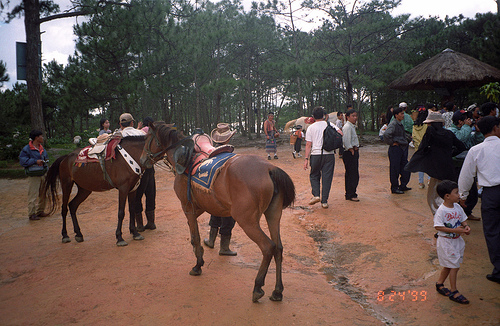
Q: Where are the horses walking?
A: On dirt.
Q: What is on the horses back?
A: Saddle.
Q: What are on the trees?
A: Gree leaves.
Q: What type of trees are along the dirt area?
A: Pine trees.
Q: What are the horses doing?
A: Standing.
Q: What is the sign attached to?
A: A tree.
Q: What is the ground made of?
A: Red clay.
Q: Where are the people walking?
A: On red clay.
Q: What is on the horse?
A: A saddle.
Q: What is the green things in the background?
A: Trees.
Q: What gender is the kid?
A: A boy.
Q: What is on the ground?
A: Dirt.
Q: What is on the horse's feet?
A: Horse shoes.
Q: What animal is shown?
A: Horses.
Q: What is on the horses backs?
A: Saddles.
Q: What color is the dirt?
A: Red.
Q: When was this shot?
A: Daytime.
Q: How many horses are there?
A: 2.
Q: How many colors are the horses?
A: 1.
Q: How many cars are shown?
A: 0.